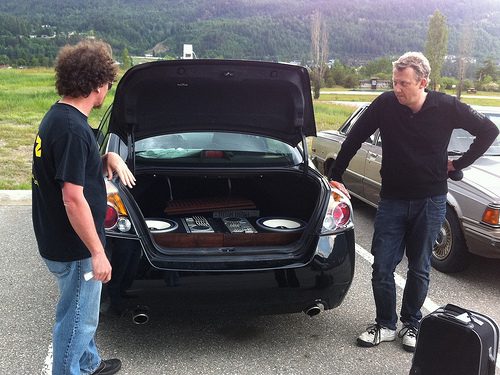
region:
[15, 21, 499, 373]
two more or less middle aged dudes stare at stereo stuff in car trunk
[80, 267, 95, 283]
dude on left has key [visible keychain] in hand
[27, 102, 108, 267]
guy on left wears black t-shirt w/ yellow print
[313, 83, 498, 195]
man on right wearing long sleeved small v-neck sweater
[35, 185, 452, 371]
both dudes wear some kind of denim pants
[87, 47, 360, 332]
car is black w/ reasonably flashy taillights. hood is up, is stereo stuff theirs? who can know, at least from photo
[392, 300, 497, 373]
small black suitcase right front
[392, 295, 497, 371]
small black suitcase has small black handle, silvertone trim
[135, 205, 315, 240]
two round+ heavy for home speakers in that trunk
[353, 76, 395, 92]
building in the distance, [in]directly to the right of older guy's face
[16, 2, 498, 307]
these men are observing speakers in their trunk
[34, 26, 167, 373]
this man is inspecting the speakers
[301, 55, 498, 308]
this guy is showing off his sound system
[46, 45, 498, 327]
they might be parked at a public place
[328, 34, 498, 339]
this guy looks like he is trying to prove something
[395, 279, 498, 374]
the luggage is on the ground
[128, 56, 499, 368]
this man looks upset that speakers are in the trunk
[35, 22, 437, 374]
the guy in the t-shirt could be in trouble for putting speakers in the trunk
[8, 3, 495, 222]
they are parked in an open country location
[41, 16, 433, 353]
the older guy might not like what the younger guy has done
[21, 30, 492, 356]
Two people looking inside a car truck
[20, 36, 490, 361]
A man showing his friend his car speakers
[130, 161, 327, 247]
Speakers inside of a car trunk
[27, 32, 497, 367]
A man showing his friend his new stereo speakers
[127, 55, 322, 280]
A car with its trunk open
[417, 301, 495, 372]
Black suitcase packed for a trip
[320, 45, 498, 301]
Man standing beside someone's car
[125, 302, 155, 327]
Muffler pipe of a car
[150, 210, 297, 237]
Two big speakers beside each other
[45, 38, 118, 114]
Person with brown curly hair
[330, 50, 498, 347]
man in dark shirt and dark blue jeans to the right of black car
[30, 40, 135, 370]
man with curly brown hair to the left of the car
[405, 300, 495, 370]
dark suitcase near man in white athletic shoes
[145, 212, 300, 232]
sound system in trunk of black car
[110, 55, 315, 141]
black car's open trunk lid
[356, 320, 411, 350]
white athletic shoes of man with hand on car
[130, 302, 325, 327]
mufflers on back of dark colored car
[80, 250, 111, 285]
man to left of car's hand holding something white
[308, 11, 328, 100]
tree without top leaves right of the black car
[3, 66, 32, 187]
field to left of man holding white thing in his hand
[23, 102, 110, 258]
the man is wearing a t shirt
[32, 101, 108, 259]
the t shirt is black in color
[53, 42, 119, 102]
the man has curly hair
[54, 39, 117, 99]
the man's hair is dark brown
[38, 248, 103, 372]
the man is wearing jeans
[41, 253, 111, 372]
the jeans are blue in color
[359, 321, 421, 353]
the man is wearing athletic shoes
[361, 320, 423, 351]
the shoes are white in color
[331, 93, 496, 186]
the man is wearing a v neck shirt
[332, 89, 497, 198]
the shirt is black in color